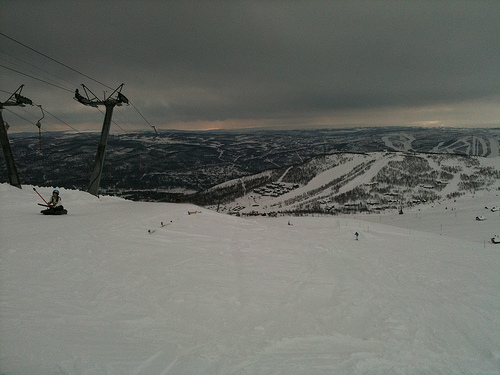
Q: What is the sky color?
A: Gray.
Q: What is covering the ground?
A: Snow.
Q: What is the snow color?
A: White.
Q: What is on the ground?
A: Snow.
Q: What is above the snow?
A: Sky.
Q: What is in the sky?
A: Storm clouds.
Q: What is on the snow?
A: People skiing.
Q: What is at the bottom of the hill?
A: Trees.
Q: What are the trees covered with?
A: Snow.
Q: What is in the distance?
A: Mountains.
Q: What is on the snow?
A: Tracks from people.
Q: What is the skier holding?
A: Skis.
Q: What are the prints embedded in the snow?
A: Tracks.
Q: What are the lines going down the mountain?
A: Power lines.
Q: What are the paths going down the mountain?
A: Ski paths.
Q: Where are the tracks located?
A: In snow.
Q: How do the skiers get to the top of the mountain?
A: Ski lift.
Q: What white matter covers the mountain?
A: Snow.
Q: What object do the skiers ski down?
A: Ski slope.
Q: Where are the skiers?
A: On slopes.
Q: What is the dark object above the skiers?
A: Sky.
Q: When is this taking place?
A: Daytime.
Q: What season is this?
A: Winter.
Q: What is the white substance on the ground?
A: Snow.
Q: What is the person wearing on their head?
A: Hat.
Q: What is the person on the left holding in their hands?
A: Ski pole.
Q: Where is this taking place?
A: Ski slope.